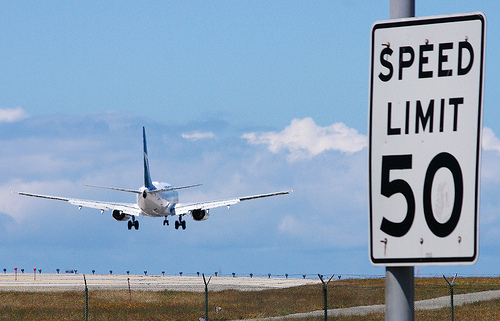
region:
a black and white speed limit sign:
[352, 8, 498, 280]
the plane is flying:
[1, 118, 312, 271]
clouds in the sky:
[5, 92, 362, 215]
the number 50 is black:
[367, 140, 471, 256]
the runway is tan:
[7, 257, 342, 304]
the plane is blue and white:
[9, 115, 311, 248]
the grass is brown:
[6, 267, 496, 319]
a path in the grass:
[270, 277, 496, 317]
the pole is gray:
[372, 3, 437, 316]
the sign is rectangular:
[357, 11, 490, 274]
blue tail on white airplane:
[141, 124, 154, 192]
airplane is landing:
[15, 125, 293, 231]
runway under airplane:
[1, 273, 334, 288]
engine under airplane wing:
[189, 207, 211, 221]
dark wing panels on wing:
[238, 191, 290, 202]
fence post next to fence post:
[317, 272, 338, 319]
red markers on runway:
[31, 266, 38, 283]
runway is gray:
[2, 272, 337, 298]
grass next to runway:
[1, 276, 498, 319]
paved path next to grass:
[250, 288, 395, 319]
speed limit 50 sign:
[369, 15, 486, 275]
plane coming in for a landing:
[6, 100, 286, 305]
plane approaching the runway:
[19, 120, 283, 292]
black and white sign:
[361, 7, 496, 298]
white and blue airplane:
[0, 113, 308, 246]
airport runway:
[3, 240, 300, 320]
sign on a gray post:
[361, 1, 496, 319]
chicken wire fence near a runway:
[67, 255, 239, 320]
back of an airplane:
[16, 118, 288, 250]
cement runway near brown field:
[2, 240, 374, 320]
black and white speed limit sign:
[364, 13, 483, 270]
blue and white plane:
[16, 123, 295, 237]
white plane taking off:
[4, 121, 296, 235]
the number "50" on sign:
[377, 146, 465, 239]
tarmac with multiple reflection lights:
[4, 260, 329, 300]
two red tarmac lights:
[10, 265, 40, 282]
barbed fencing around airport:
[34, 271, 492, 316]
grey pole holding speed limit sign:
[386, 3, 418, 318]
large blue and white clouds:
[6, 106, 365, 253]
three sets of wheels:
[124, 214, 190, 233]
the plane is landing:
[7, 123, 303, 233]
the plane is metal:
[17, 123, 289, 236]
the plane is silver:
[21, 189, 126, 211]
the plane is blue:
[138, 126, 158, 186]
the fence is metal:
[195, 267, 232, 317]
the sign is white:
[367, 9, 482, 263]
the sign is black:
[365, 16, 497, 266]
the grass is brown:
[237, 292, 292, 309]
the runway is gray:
[81, 270, 171, 287]